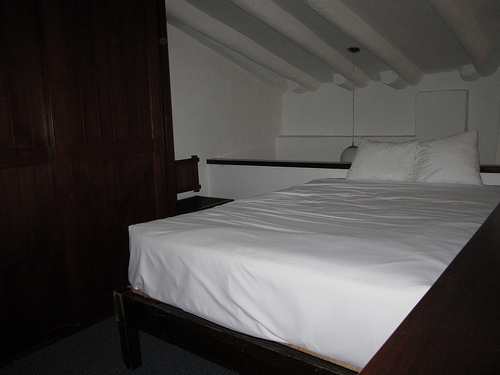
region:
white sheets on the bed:
[123, 148, 496, 369]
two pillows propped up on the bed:
[341, 133, 485, 188]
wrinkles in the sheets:
[208, 178, 402, 235]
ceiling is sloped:
[167, 3, 498, 104]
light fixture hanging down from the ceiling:
[338, 48, 359, 168]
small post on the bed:
[106, 278, 149, 370]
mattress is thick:
[116, 214, 434, 374]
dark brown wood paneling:
[3, 49, 183, 368]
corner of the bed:
[113, 220, 153, 371]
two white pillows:
[340, 129, 487, 187]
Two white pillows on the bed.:
[345, 130, 497, 190]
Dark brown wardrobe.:
[6, 2, 196, 219]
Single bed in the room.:
[120, 127, 496, 346]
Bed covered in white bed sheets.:
[112, 154, 493, 363]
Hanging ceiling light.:
[335, 67, 367, 172]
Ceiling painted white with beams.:
[172, 2, 497, 99]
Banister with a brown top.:
[202, 150, 284, 197]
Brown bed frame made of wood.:
[100, 277, 355, 374]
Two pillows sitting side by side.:
[337, 133, 490, 185]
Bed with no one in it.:
[110, 130, 497, 368]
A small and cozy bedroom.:
[14, 4, 498, 373]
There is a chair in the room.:
[173, 151, 231, 211]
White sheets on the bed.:
[129, 176, 498, 315]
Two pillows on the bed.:
[348, 135, 488, 187]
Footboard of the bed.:
[103, 288, 347, 374]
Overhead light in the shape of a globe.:
[338, 142, 360, 165]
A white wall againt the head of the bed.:
[209, 163, 499, 197]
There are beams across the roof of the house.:
[178, 8, 494, 93]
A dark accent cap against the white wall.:
[201, 156, 355, 170]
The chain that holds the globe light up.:
[346, 55, 355, 147]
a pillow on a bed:
[333, 107, 485, 192]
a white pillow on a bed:
[338, 103, 495, 203]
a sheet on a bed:
[143, 79, 454, 308]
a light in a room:
[330, 43, 384, 171]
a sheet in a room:
[197, 162, 397, 367]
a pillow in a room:
[340, 120, 450, 191]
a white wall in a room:
[275, 87, 390, 142]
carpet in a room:
[66, 311, 142, 368]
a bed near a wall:
[86, 85, 451, 333]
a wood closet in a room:
[38, 64, 313, 326]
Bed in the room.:
[110, 128, 497, 373]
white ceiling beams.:
[162, 0, 497, 90]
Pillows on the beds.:
[340, 130, 490, 180]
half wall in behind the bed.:
[205, 150, 495, 195]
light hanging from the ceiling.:
[336, 86, 364, 167]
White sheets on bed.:
[121, 162, 497, 372]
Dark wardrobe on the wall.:
[0, 0, 195, 370]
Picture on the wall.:
[171, 155, 207, 197]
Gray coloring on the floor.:
[10, 303, 230, 371]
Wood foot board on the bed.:
[104, 287, 349, 374]